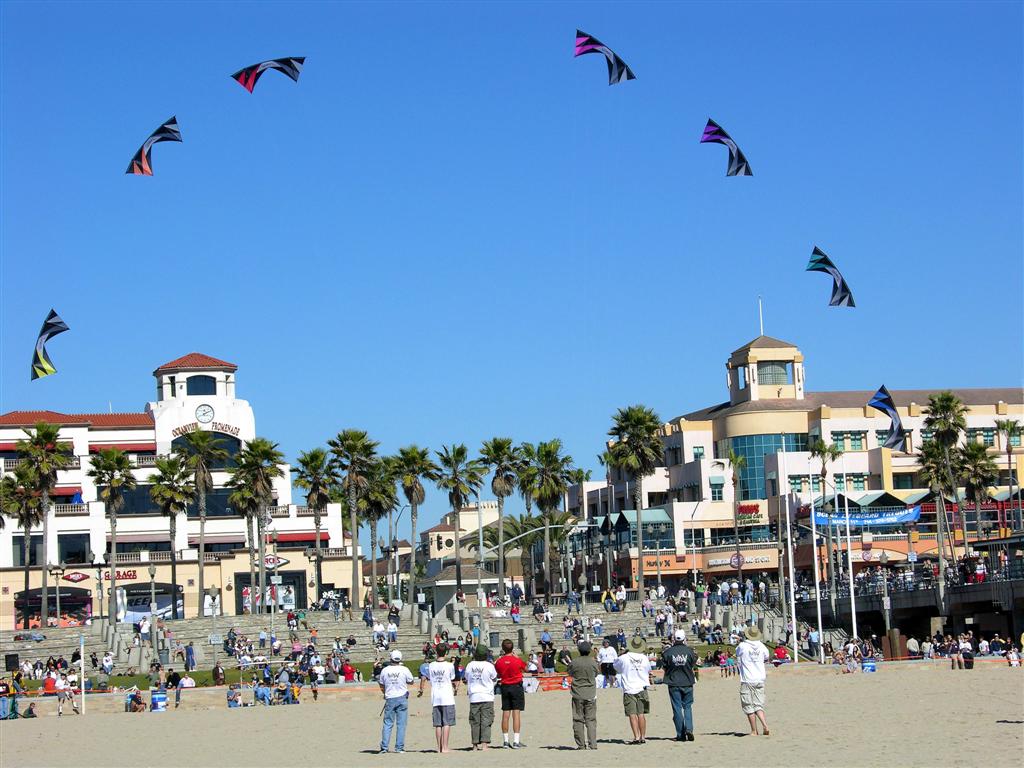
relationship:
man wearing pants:
[358, 648, 423, 765] [375, 692, 414, 753]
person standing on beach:
[715, 614, 808, 729] [836, 692, 957, 727]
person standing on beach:
[358, 655, 423, 740] [827, 675, 880, 730]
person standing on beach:
[375, 647, 411, 753] [853, 687, 953, 750]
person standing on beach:
[375, 647, 411, 753] [836, 696, 940, 744]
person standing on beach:
[717, 625, 791, 753] [835, 683, 983, 753]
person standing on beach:
[345, 618, 415, 753] [831, 713, 968, 755]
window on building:
[60, 536, 125, 575] [0, 336, 331, 607]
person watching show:
[654, 629, 706, 741] [26, 74, 966, 733]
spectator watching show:
[660, 610, 706, 725] [67, 94, 973, 710]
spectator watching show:
[660, 588, 710, 744] [26, 74, 966, 733]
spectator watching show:
[669, 616, 706, 722] [84, 42, 890, 743]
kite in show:
[119, 111, 189, 187] [16, 20, 920, 486]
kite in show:
[225, 55, 308, 103] [16, 20, 920, 486]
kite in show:
[568, 24, 640, 94] [16, 20, 920, 486]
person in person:
[717, 623, 785, 744] [729, 624, 775, 737]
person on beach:
[717, 623, 785, 744] [9, 662, 990, 764]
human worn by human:
[614, 636, 653, 744] [605, 636, 658, 751]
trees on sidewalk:
[9, 402, 668, 606] [17, 604, 828, 674]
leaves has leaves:
[0, 419, 143, 524] [32, 436, 58, 484]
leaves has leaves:
[381, 444, 442, 505] [404, 447, 418, 473]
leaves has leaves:
[291, 445, 332, 489] [311, 458, 333, 495]